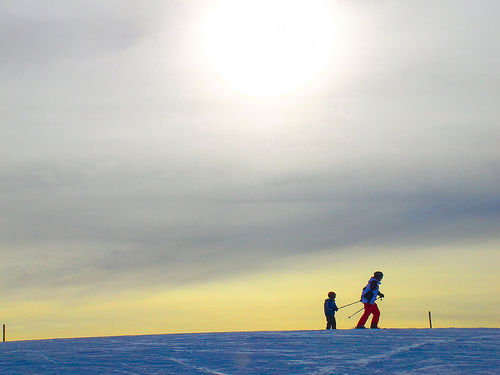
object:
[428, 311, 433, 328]
stick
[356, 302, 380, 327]
pants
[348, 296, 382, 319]
pole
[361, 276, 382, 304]
jacket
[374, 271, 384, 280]
helmet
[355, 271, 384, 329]
adult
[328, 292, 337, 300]
helmet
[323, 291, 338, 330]
child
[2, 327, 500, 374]
snow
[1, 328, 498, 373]
ground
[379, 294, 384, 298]
glove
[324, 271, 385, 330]
people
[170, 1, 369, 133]
sun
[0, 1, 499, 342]
sky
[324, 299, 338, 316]
coat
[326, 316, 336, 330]
pants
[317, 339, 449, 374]
line